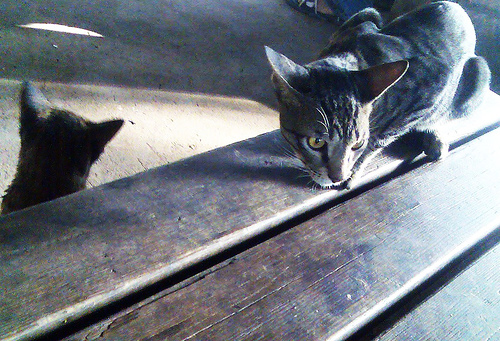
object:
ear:
[91, 116, 123, 151]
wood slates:
[0, 83, 499, 337]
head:
[15, 80, 124, 167]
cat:
[0, 81, 126, 218]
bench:
[0, 90, 499, 340]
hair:
[263, 2, 488, 192]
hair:
[0, 80, 124, 216]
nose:
[324, 161, 349, 184]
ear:
[262, 44, 309, 106]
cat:
[262, 0, 490, 191]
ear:
[17, 80, 55, 133]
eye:
[306, 136, 325, 150]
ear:
[355, 60, 410, 107]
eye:
[347, 140, 364, 152]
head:
[261, 45, 410, 189]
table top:
[0, 87, 499, 340]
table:
[0, 89, 499, 339]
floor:
[0, 0, 499, 214]